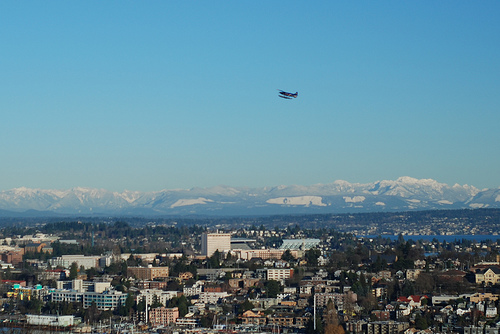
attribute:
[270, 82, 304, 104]
plane — black 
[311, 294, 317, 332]
pole — white 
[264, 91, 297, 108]
gear — landing, for water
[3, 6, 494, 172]
sky — blue 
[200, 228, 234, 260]
building — white 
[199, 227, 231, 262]
building — tallest 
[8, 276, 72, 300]
mounds — green